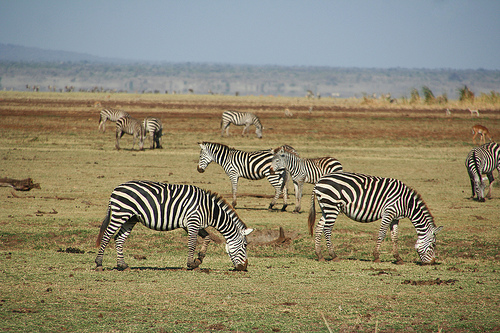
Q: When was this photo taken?
A: Daytime.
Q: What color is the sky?
A: Gray.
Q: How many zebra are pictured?
A: 9.